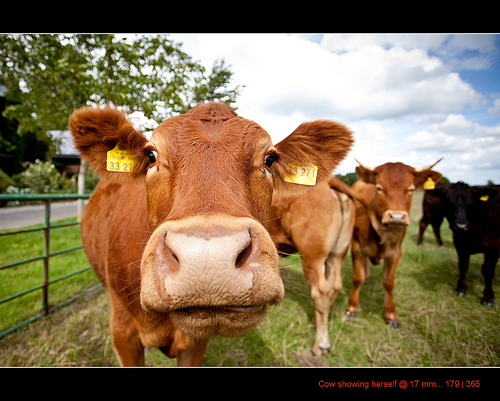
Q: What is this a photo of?
A: Cattle.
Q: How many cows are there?
A: Five.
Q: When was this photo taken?
A: During the spring or summer.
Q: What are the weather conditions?
A: Partly cloudy.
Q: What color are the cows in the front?
A: Brown.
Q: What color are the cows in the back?
A: Black.